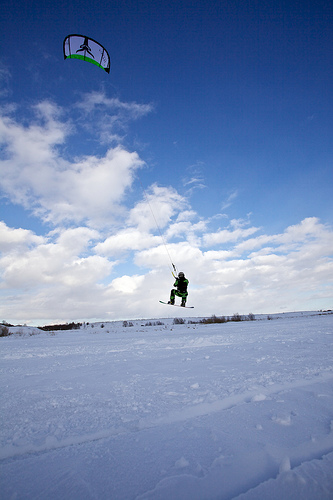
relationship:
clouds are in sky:
[4, 90, 331, 315] [2, 2, 333, 321]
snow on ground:
[6, 327, 332, 493] [0, 308, 332, 499]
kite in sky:
[47, 26, 117, 77] [2, 2, 333, 321]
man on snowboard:
[162, 264, 197, 304] [156, 295, 203, 313]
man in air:
[162, 264, 197, 304] [126, 293, 231, 322]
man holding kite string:
[162, 264, 197, 304] [121, 162, 184, 280]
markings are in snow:
[13, 384, 331, 498] [6, 327, 332, 493]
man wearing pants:
[162, 264, 197, 304] [164, 288, 194, 308]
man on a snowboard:
[162, 264, 197, 304] [156, 295, 203, 313]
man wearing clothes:
[162, 264, 197, 304] [162, 278, 201, 305]